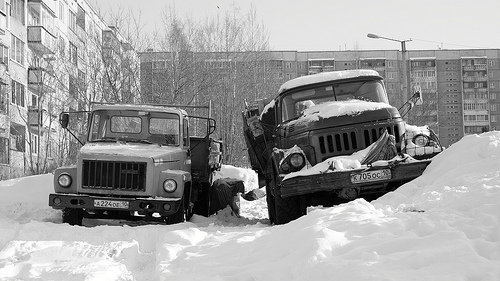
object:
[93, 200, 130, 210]
plate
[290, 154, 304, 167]
light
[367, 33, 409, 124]
light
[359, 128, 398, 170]
trash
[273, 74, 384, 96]
roof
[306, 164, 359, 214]
ground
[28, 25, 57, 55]
balcony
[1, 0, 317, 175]
trees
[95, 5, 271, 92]
zebra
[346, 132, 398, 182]
ground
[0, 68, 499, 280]
snow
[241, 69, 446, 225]
old vehicle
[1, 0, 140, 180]
apartment building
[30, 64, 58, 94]
balcony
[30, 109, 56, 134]
balcony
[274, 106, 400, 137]
hood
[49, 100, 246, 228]
truck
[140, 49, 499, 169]
building